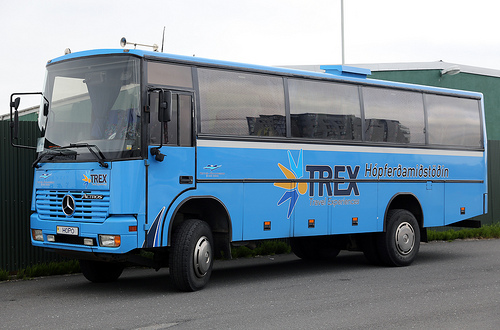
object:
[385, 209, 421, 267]
tire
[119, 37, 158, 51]
horn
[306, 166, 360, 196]
trex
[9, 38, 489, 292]
bonus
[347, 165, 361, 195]
black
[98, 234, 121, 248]
headlight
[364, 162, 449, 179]
letter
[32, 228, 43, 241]
headlight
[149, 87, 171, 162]
rearview mirror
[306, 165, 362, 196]
letter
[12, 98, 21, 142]
mirror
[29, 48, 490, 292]
bus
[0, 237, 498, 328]
road